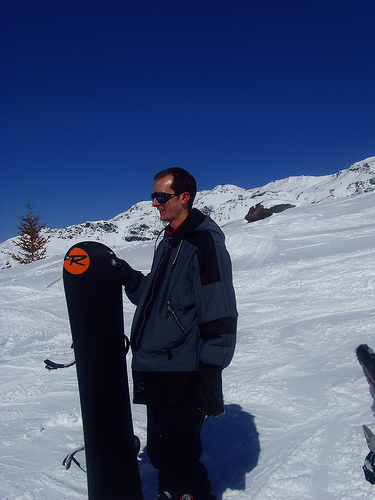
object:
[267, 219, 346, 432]
ground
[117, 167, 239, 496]
man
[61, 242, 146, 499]
board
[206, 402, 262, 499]
shadow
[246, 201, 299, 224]
rock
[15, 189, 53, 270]
tree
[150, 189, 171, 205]
sunglasses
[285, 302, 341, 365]
snow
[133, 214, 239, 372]
coat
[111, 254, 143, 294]
glove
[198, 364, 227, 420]
glove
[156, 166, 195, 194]
hair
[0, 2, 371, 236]
sky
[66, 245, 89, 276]
logo